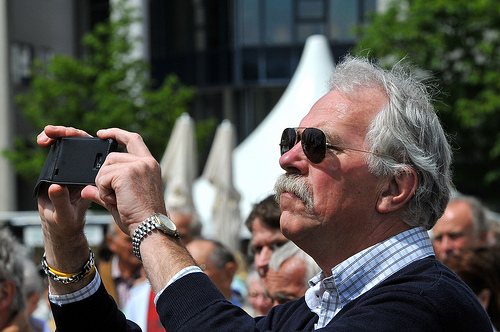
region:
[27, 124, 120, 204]
small black digital camera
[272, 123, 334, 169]
black glass aviator style sunglasses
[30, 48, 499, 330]
man holding camera up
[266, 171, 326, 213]
gray mustache on man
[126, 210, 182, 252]
silver and gold watch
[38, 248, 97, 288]
men's silver bracelet on right wrist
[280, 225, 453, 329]
men's button down shirt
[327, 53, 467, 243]
silver gray hair on man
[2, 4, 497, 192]
tall building in background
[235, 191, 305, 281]
brown haired man looking around gray haired man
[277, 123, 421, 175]
dark sunglasses with thin frames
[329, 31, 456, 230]
man's gray hair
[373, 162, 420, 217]
left ear of a white man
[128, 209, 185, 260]
metal watch with a silver color band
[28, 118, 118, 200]
black camera phone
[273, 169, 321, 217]
man's gray mustache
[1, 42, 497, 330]
older man taking a picture with his phone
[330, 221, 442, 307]
checkered collar on a shirt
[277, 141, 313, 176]
slightly red nose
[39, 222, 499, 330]
sweater with a checkered shirt underneath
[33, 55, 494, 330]
Man holding up a cell phone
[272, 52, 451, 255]
Man with gray hair and a gray mustache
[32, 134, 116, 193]
Cell phone with camera and case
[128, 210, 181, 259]
Silver wrist watch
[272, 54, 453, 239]
Man with dark sunglasses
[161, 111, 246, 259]
Two collapsed white umbrellas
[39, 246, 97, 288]
Silver bracelet and yellow wrist band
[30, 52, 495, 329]
Man wearing a shirt with collar and a sweater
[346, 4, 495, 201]
Green tree behind a man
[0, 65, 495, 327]
A crowd of people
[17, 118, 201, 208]
hands holding a Carma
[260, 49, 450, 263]
man with glass on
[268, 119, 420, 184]
a pair of sunglasses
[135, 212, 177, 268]
a wrist watch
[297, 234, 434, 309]
a white and blue checkered shirt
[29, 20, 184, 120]
green leafy trees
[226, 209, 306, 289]
a crowd of people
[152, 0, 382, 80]
a building with windows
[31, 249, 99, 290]
a black and white bracelet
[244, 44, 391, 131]
top of a tent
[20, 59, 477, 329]
a man holding a cell phone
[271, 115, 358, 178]
A man wearing sunglasses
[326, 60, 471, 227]
A man with gray hair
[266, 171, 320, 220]
A man with a moustache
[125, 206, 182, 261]
A man wearing a watch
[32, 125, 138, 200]
A cell phone in a man's hands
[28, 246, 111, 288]
A man wearing bracelets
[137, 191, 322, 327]
People in the distance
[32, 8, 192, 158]
A tree in the distance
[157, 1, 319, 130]
A building in the distance